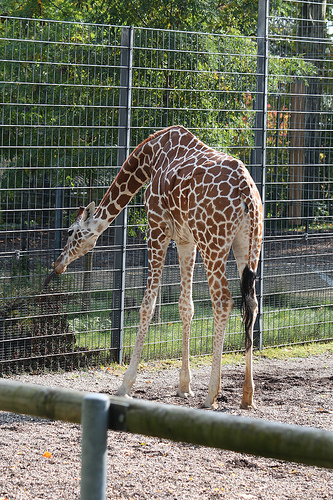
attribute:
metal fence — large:
[128, 23, 331, 107]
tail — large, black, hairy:
[235, 183, 261, 355]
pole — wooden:
[4, 374, 332, 468]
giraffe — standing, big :
[47, 124, 264, 410]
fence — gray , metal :
[0, 2, 319, 377]